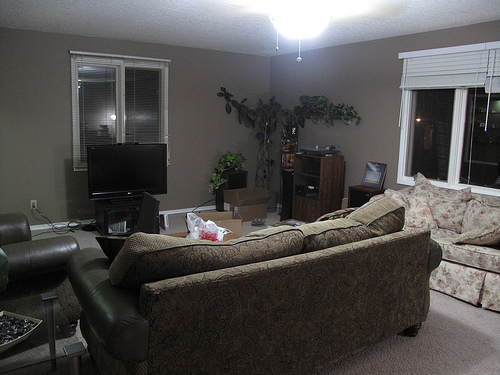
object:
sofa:
[67, 194, 442, 375]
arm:
[64, 247, 151, 364]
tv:
[86, 142, 168, 202]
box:
[223, 186, 274, 223]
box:
[191, 211, 243, 242]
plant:
[207, 151, 248, 194]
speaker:
[216, 168, 249, 212]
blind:
[397, 41, 490, 89]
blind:
[484, 41, 500, 132]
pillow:
[384, 184, 437, 231]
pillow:
[454, 222, 500, 246]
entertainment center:
[93, 191, 160, 236]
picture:
[361, 160, 387, 190]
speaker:
[347, 185, 371, 207]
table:
[0, 289, 91, 374]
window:
[398, 88, 500, 200]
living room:
[0, 0, 500, 375]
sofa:
[381, 173, 500, 316]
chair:
[0, 208, 81, 337]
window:
[71, 51, 170, 170]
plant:
[215, 85, 292, 215]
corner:
[241, 54, 290, 212]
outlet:
[30, 199, 37, 210]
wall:
[0, 29, 272, 233]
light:
[267, 11, 333, 42]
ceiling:
[173, 1, 390, 57]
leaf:
[225, 102, 232, 115]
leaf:
[240, 97, 246, 104]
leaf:
[216, 92, 224, 97]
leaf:
[224, 91, 233, 98]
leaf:
[238, 111, 243, 124]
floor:
[317, 286, 498, 375]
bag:
[184, 213, 233, 243]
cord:
[33, 207, 97, 236]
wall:
[271, 19, 500, 223]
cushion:
[106, 225, 304, 290]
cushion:
[299, 194, 407, 254]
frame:
[70, 51, 170, 172]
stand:
[291, 145, 346, 223]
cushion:
[409, 171, 472, 233]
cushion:
[462, 199, 499, 234]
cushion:
[449, 229, 500, 258]